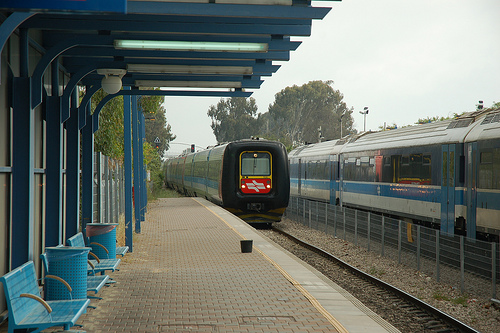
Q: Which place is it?
A: It is a train station.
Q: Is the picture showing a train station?
A: Yes, it is showing a train station.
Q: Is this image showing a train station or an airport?
A: It is showing a train station.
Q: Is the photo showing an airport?
A: No, the picture is showing a train station.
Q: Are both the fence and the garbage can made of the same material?
A: Yes, both the fence and the garbage can are made of metal.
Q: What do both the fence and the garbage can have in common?
A: The material, both the fence and the garbage can are metallic.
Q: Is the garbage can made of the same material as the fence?
A: Yes, both the garbage can and the fence are made of metal.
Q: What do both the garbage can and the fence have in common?
A: The material, both the garbage can and the fence are metallic.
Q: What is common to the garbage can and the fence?
A: The material, both the garbage can and the fence are metallic.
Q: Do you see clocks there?
A: No, there are no clocks.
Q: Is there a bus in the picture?
A: No, there are no buses.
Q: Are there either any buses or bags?
A: No, there are no buses or bags.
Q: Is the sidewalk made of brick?
A: Yes, the sidewalk is made of brick.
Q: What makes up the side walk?
A: The side walk is made of brick.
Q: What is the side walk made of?
A: The side walk is made of brick.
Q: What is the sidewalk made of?
A: The side walk is made of brick.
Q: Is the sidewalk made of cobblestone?
A: No, the sidewalk is made of brick.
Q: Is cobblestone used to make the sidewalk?
A: No, the sidewalk is made of brick.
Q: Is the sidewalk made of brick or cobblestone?
A: The sidewalk is made of brick.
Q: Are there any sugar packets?
A: No, there are no sugar packets.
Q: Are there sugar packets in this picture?
A: No, there are no sugar packets.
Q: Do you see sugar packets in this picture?
A: No, there are no sugar packets.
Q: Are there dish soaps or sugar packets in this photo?
A: No, there are no sugar packets or dish soaps.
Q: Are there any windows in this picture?
A: Yes, there is a window.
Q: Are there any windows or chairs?
A: Yes, there is a window.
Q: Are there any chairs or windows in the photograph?
A: Yes, there is a window.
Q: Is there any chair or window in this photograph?
A: Yes, there is a window.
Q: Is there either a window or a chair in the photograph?
A: Yes, there is a window.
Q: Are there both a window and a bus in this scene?
A: No, there is a window but no buses.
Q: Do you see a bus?
A: No, there are no buses.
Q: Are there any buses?
A: No, there are no buses.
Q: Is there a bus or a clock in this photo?
A: No, there are no buses or clocks.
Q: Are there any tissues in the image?
A: No, there are no tissues.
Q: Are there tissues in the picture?
A: No, there are no tissues.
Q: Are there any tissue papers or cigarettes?
A: No, there are no tissue papers or cigarettes.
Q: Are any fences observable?
A: Yes, there is a fence.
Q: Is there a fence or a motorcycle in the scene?
A: Yes, there is a fence.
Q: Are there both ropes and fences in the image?
A: No, there is a fence but no ropes.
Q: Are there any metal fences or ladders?
A: Yes, there is a metal fence.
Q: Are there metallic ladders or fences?
A: Yes, there is a metal fence.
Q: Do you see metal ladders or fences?
A: Yes, there is a metal fence.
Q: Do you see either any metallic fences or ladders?
A: Yes, there is a metal fence.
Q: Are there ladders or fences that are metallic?
A: Yes, the fence is metallic.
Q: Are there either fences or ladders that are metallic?
A: Yes, the fence is metallic.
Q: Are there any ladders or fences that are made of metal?
A: Yes, the fence is made of metal.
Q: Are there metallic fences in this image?
A: Yes, there is a metal fence.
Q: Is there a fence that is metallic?
A: Yes, there is a fence that is metallic.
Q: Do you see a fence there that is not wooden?
A: Yes, there is a metallic fence.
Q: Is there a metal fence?
A: Yes, there is a fence that is made of metal.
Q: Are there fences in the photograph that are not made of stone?
A: Yes, there is a fence that is made of metal.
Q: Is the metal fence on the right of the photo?
A: Yes, the fence is on the right of the image.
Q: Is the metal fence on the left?
A: No, the fence is on the right of the image.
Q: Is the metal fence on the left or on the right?
A: The fence is on the right of the image.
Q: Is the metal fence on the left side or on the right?
A: The fence is on the right of the image.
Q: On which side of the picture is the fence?
A: The fence is on the right of the image.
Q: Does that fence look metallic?
A: Yes, the fence is metallic.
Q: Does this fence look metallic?
A: Yes, the fence is metallic.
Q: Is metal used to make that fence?
A: Yes, the fence is made of metal.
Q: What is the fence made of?
A: The fence is made of metal.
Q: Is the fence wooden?
A: No, the fence is metallic.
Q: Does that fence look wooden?
A: No, the fence is metallic.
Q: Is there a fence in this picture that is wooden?
A: No, there is a fence but it is metallic.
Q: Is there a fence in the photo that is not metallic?
A: No, there is a fence but it is metallic.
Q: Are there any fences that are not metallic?
A: No, there is a fence but it is metallic.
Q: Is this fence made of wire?
A: No, the fence is made of metal.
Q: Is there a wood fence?
A: No, there is a fence but it is made of metal.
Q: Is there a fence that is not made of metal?
A: No, there is a fence but it is made of metal.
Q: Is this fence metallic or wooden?
A: The fence is metallic.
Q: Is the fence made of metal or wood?
A: The fence is made of metal.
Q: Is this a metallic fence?
A: Yes, this is a metallic fence.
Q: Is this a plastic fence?
A: No, this is a metallic fence.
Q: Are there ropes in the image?
A: No, there are no ropes.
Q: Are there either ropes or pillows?
A: No, there are no ropes or pillows.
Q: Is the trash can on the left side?
A: Yes, the trash can is on the left of the image.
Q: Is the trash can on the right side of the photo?
A: No, the trash can is on the left of the image.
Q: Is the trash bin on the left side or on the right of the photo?
A: The trash bin is on the left of the image.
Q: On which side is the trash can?
A: The trash can is on the left of the image.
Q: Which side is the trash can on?
A: The trash can is on the left of the image.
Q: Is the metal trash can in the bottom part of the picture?
A: Yes, the trash bin is in the bottom of the image.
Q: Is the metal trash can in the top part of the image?
A: No, the garbage can is in the bottom of the image.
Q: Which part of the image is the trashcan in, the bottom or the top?
A: The trashcan is in the bottom of the image.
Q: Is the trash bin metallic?
A: Yes, the trash bin is metallic.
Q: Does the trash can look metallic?
A: Yes, the trash can is metallic.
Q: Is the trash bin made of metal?
A: Yes, the trash bin is made of metal.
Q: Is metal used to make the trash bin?
A: Yes, the trash bin is made of metal.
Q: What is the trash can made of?
A: The trash can is made of metal.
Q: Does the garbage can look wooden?
A: No, the garbage can is metallic.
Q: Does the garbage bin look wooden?
A: No, the garbage bin is metallic.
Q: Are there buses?
A: No, there are no buses.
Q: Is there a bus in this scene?
A: No, there are no buses.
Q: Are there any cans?
A: Yes, there is a can.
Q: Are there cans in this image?
A: Yes, there is a can.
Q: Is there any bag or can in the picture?
A: Yes, there is a can.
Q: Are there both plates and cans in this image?
A: No, there is a can but no plates.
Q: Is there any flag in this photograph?
A: No, there are no flags.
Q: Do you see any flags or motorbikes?
A: No, there are no flags or motorbikes.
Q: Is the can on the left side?
A: Yes, the can is on the left of the image.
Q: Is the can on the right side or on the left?
A: The can is on the left of the image.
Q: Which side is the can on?
A: The can is on the left of the image.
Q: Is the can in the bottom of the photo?
A: Yes, the can is in the bottom of the image.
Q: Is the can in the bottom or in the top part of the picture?
A: The can is in the bottom of the image.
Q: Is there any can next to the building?
A: Yes, there is a can next to the building.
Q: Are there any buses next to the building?
A: No, there is a can next to the building.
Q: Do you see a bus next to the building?
A: No, there is a can next to the building.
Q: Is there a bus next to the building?
A: No, there is a can next to the building.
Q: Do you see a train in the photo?
A: Yes, there is a train.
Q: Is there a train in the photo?
A: Yes, there is a train.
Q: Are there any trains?
A: Yes, there is a train.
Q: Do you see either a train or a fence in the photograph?
A: Yes, there is a train.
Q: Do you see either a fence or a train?
A: Yes, there is a train.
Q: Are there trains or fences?
A: Yes, there is a train.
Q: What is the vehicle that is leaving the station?
A: The vehicle is a train.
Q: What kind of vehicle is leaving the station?
A: The vehicle is a train.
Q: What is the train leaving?
A: The train is leaving the station.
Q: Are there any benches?
A: Yes, there is a bench.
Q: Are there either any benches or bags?
A: Yes, there is a bench.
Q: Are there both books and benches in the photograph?
A: No, there is a bench but no books.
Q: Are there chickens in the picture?
A: No, there are no chickens.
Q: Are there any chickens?
A: No, there are no chickens.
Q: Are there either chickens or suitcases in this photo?
A: No, there are no chickens or suitcases.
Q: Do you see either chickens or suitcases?
A: No, there are no chickens or suitcases.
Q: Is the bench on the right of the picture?
A: No, the bench is on the left of the image.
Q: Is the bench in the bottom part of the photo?
A: Yes, the bench is in the bottom of the image.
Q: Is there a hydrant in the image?
A: No, there are no fire hydrants.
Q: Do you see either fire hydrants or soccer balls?
A: No, there are no fire hydrants or soccer balls.